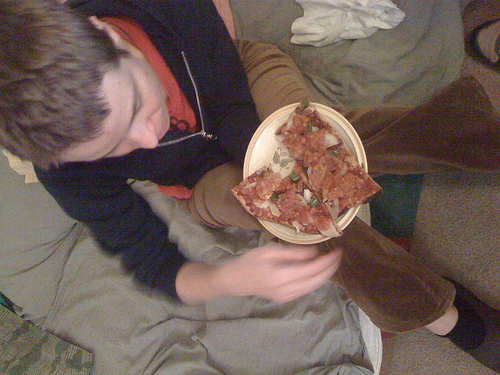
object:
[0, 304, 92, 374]
cushion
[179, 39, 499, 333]
pants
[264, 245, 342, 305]
fingers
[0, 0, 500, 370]
guy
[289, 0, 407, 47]
towel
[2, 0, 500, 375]
couch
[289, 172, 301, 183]
topping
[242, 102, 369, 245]
plate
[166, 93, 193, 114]
red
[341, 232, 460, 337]
leg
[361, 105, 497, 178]
leg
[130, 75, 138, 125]
eye brow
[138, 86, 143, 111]
eyelashes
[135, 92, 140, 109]
eyelid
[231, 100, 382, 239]
food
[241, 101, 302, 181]
edge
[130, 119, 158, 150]
nose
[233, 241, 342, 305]
hand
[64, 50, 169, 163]
face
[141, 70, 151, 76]
pimple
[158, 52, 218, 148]
zipper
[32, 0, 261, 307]
jacket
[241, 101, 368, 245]
tan plate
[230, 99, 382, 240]
pizza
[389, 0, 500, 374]
rug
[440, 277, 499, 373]
loafer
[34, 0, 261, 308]
sweater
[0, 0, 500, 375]
bed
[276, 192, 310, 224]
meat chunk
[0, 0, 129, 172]
hair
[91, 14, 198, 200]
shirt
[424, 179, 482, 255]
floor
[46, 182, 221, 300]
arm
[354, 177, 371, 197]
sauce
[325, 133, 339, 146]
cheese